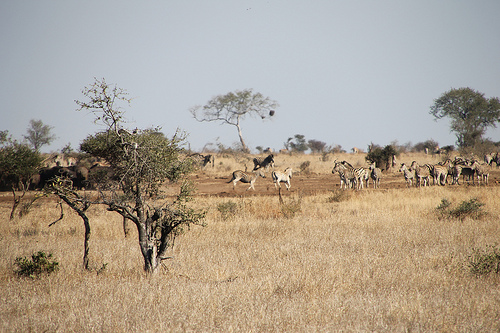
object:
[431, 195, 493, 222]
bush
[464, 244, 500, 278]
bush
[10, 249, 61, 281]
bush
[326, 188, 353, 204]
bush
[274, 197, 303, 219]
bush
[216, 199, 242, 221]
bush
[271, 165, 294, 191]
animals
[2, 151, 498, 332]
ground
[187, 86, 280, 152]
tree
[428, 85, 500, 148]
tree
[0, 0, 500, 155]
sky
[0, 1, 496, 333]
plains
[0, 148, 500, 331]
brown grass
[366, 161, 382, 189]
zebras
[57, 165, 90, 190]
animals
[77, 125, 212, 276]
trees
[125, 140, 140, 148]
nest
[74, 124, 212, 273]
tree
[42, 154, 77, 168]
rock formation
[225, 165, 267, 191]
zebra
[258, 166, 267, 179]
head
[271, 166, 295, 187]
zebra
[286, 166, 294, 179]
head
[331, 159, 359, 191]
zebra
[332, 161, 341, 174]
head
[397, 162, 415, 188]
zebra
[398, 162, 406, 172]
head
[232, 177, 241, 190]
legs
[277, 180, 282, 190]
legs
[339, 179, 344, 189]
legs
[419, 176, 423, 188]
legs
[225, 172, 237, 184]
tail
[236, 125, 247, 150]
trunk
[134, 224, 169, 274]
trunk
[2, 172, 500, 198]
trail